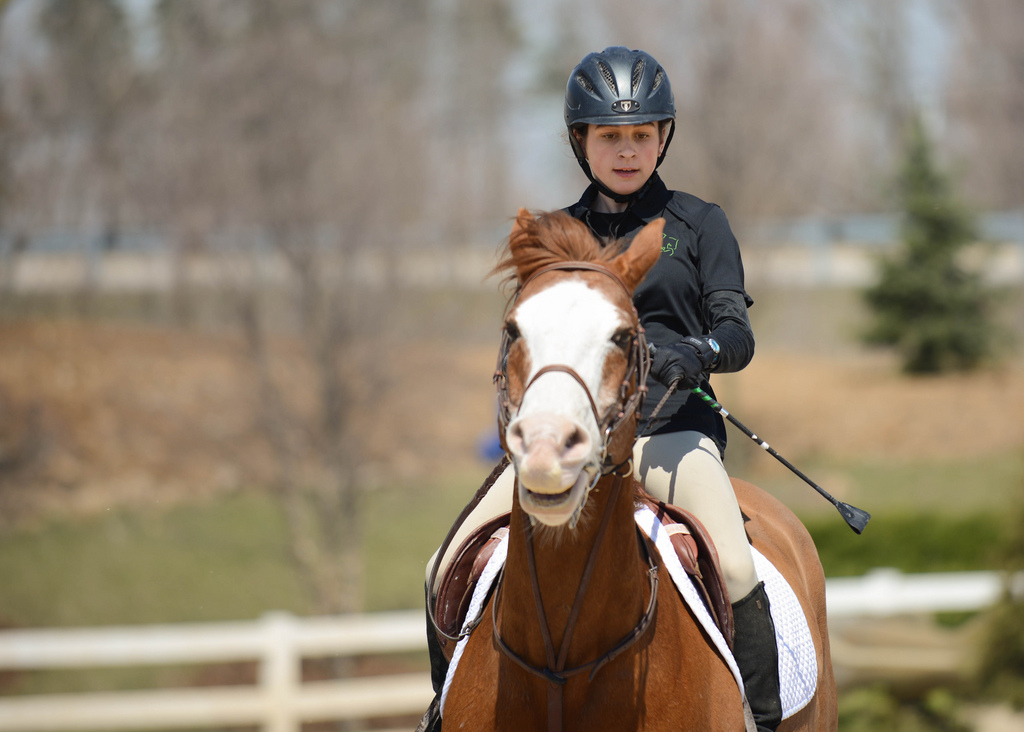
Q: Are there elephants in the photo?
A: No, there are no elephants.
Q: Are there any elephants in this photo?
A: No, there are no elephants.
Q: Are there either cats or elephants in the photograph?
A: No, there are no elephants or cats.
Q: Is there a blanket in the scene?
A: Yes, there is a blanket.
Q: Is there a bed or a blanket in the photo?
A: Yes, there is a blanket.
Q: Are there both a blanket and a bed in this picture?
A: No, there is a blanket but no beds.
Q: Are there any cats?
A: No, there are no cats.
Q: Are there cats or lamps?
A: No, there are no cats or lamps.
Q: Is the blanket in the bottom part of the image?
A: Yes, the blanket is in the bottom of the image.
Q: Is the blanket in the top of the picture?
A: No, the blanket is in the bottom of the image.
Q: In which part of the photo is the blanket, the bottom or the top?
A: The blanket is in the bottom of the image.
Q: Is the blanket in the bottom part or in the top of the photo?
A: The blanket is in the bottom of the image.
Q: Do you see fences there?
A: Yes, there is a fence.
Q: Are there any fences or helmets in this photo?
A: Yes, there is a fence.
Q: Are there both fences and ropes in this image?
A: No, there is a fence but no ropes.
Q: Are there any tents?
A: No, there are no tents.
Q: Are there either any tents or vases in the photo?
A: No, there are no tents or vases.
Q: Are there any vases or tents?
A: No, there are no tents or vases.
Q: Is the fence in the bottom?
A: Yes, the fence is in the bottom of the image.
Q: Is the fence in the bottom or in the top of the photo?
A: The fence is in the bottom of the image.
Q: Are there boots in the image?
A: Yes, there are boots.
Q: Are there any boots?
A: Yes, there are boots.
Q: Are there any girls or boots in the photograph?
A: Yes, there are boots.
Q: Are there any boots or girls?
A: Yes, there are boots.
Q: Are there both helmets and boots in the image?
A: Yes, there are both boots and a helmet.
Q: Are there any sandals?
A: No, there are no sandals.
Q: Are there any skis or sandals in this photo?
A: No, there are no sandals or skis.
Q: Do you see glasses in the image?
A: No, there are no glasses.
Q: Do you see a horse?
A: Yes, there is a horse.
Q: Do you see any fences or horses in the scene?
A: Yes, there is a horse.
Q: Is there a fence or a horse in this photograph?
A: Yes, there is a horse.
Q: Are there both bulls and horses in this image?
A: No, there is a horse but no bulls.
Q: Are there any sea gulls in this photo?
A: No, there are no sea gulls.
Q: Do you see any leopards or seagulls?
A: No, there are no seagulls or leopards.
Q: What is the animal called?
A: The animal is a horse.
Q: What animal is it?
A: The animal is a horse.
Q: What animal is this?
A: This is a horse.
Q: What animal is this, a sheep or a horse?
A: This is a horse.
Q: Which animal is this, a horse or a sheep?
A: This is a horse.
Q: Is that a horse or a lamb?
A: That is a horse.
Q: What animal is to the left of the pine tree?
A: The animal is a horse.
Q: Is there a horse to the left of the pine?
A: Yes, there is a horse to the left of the pine.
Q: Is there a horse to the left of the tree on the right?
A: Yes, there is a horse to the left of the pine.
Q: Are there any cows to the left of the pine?
A: No, there is a horse to the left of the pine.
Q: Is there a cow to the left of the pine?
A: No, there is a horse to the left of the pine.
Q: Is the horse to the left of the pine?
A: Yes, the horse is to the left of the pine.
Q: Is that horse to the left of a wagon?
A: No, the horse is to the left of the pine.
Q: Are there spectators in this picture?
A: No, there are no spectators.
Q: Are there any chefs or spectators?
A: No, there are no spectators or chefs.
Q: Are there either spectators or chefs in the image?
A: No, there are no spectators or chefs.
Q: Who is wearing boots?
A: The girl is wearing boots.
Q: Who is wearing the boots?
A: The girl is wearing boots.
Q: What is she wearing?
A: The girl is wearing boots.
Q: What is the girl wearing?
A: The girl is wearing boots.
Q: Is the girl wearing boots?
A: Yes, the girl is wearing boots.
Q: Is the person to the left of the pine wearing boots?
A: Yes, the girl is wearing boots.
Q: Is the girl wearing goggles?
A: No, the girl is wearing boots.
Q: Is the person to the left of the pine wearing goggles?
A: No, the girl is wearing boots.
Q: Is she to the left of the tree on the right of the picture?
A: Yes, the girl is to the left of the pine tree.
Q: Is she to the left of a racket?
A: No, the girl is to the left of the pine tree.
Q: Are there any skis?
A: No, there are no skis.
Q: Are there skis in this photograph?
A: No, there are no skis.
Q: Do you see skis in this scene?
A: No, there are no skis.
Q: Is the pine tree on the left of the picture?
A: No, the pine tree is on the right of the image.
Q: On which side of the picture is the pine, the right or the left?
A: The pine is on the right of the image.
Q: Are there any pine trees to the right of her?
A: Yes, there is a pine tree to the right of the girl.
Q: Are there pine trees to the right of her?
A: Yes, there is a pine tree to the right of the girl.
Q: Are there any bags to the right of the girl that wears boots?
A: No, there is a pine tree to the right of the girl.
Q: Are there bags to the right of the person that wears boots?
A: No, there is a pine tree to the right of the girl.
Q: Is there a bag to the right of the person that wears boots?
A: No, there is a pine tree to the right of the girl.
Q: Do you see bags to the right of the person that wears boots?
A: No, there is a pine tree to the right of the girl.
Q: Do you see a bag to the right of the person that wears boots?
A: No, there is a pine tree to the right of the girl.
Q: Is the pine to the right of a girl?
A: Yes, the pine is to the right of a girl.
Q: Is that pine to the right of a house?
A: No, the pine is to the right of a girl.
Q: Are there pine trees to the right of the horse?
A: Yes, there is a pine tree to the right of the horse.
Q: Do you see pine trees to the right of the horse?
A: Yes, there is a pine tree to the right of the horse.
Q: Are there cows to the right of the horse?
A: No, there is a pine tree to the right of the horse.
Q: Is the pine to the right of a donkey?
A: No, the pine is to the right of the horse.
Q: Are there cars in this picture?
A: No, there are no cars.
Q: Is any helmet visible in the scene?
A: Yes, there is a helmet.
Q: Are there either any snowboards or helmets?
A: Yes, there is a helmet.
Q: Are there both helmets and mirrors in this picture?
A: No, there is a helmet but no mirrors.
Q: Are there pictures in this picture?
A: No, there are no pictures.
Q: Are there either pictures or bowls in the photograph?
A: No, there are no pictures or bowls.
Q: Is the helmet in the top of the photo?
A: Yes, the helmet is in the top of the image.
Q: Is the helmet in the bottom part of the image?
A: No, the helmet is in the top of the image.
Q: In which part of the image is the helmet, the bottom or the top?
A: The helmet is in the top of the image.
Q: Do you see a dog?
A: No, there are no dogs.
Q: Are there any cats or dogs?
A: No, there are no dogs or cats.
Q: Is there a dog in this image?
A: No, there are no dogs.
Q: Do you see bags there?
A: No, there are no bags.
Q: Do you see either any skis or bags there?
A: No, there are no bags or skis.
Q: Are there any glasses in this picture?
A: No, there are no glasses.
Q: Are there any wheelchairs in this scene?
A: No, there are no wheelchairs.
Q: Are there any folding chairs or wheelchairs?
A: No, there are no wheelchairs or folding chairs.